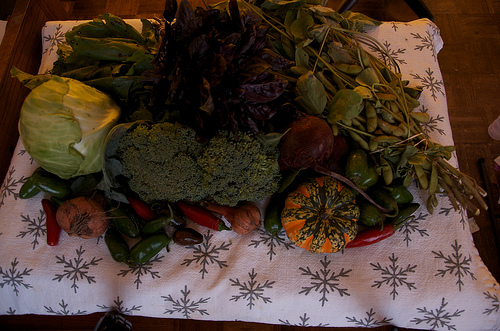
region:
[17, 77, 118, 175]
green and white head of cabbage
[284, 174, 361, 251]
round orange and green gourd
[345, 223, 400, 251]
small red chili pepper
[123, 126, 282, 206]
two dark green heads of broccoli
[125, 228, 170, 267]
dark green pepper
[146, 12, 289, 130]
dark purple leafy vegetable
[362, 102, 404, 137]
group of dark green beans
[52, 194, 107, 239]
small round pink root vegetable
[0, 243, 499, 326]
section of white table cloth with grey snowflakes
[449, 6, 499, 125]
section of brown parkay flooring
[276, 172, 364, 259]
a squash color green and orange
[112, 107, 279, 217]
green broccoli on table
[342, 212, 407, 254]
a red chili pepper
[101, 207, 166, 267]
the green chili pepper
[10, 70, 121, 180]
green cabbage next broccoli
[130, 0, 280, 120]
a purple lettuce on table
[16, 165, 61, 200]
the green chili pepper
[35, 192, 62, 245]
the red chili pepper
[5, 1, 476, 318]
a table covered with tablecloth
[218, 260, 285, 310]
snowflakes on table tablecloth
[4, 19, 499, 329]
A white pillow case with gray snowflakes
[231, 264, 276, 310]
A gray snowflake on the fabric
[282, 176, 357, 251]
A small orange gourd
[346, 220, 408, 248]
A red chili pepper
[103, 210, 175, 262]
A few green peppers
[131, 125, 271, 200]
The heads of broccoli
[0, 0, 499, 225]
A wooden floor under the pillow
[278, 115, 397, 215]
A red radish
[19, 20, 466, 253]
A pile of vegetables on a pillow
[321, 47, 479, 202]
A collection of beans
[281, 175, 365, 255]
small orange and green pumpkin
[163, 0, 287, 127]
head of red lettuce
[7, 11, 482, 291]
vegetables on a pillow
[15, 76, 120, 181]
whole head of cabbage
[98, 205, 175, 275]
four small green peppers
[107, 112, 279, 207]
two heads of broccoli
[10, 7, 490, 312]
vegetables on a cotton cloth with snowflake pattern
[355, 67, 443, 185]
green peas in a pod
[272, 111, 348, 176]
red turnip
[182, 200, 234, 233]
small red pepper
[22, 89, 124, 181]
a head of lettuce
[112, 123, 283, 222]
brocoli flowers on a pillow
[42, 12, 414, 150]
different types of vegetables mixed together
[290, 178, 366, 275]
an orange vegetable in the group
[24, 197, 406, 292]
red peppers on the pillow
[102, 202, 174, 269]
green peppers on the pillow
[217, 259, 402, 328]
this pillow has snowflake prints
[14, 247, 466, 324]
the pillow is white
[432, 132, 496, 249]
asparagus on the pillow